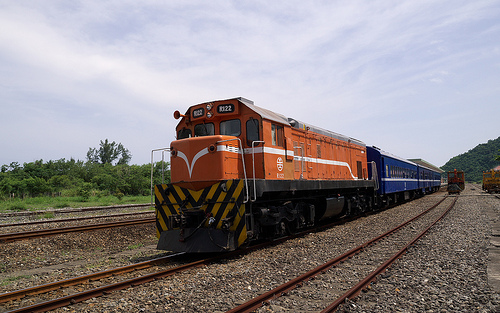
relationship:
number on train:
[216, 102, 232, 115] [152, 96, 444, 254]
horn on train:
[166, 92, 187, 128] [152, 96, 444, 254]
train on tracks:
[152, 96, 444, 254] [6, 240, 209, 311]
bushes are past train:
[2, 149, 164, 211] [171, 96, 468, 243]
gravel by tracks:
[456, 185, 497, 311] [231, 195, 458, 306]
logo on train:
[274, 155, 284, 170] [152, 96, 444, 254]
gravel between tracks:
[3, 186, 490, 311] [231, 195, 458, 306]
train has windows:
[152, 96, 444, 254] [177, 115, 261, 148]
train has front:
[152, 96, 444, 254] [149, 97, 264, 254]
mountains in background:
[437, 134, 498, 191] [1, 111, 499, 179]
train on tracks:
[252, 193, 380, 240] [2, 196, 458, 312]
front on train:
[149, 97, 264, 254] [152, 96, 444, 254]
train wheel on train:
[263, 197, 326, 244] [152, 96, 444, 254]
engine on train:
[148, 95, 367, 257] [145, 93, 472, 253]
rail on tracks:
[304, 187, 456, 312] [2, 177, 462, 309]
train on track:
[152, 96, 444, 254] [0, 251, 216, 311]